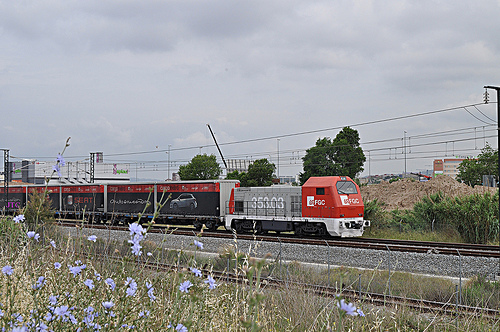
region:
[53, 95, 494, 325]
a train on tracks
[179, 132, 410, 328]
tracks with a train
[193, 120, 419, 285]
train tracks with a train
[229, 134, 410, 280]
a silver and red train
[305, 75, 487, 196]
power lines in the air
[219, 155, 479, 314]
train tracks with rocks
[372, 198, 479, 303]
rocks surrounding tracks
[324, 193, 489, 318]
rocks surround train tracks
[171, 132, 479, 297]
train tracks with train cars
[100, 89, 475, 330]
train cars on a track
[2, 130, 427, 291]
Train moving through the countryside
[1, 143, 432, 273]
Freight train delivering goods to a city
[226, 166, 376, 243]
Locomotive of a freight train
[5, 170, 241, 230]
Boxcars of a freight train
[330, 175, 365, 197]
Windshield of a freight train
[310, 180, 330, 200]
Window of a freight train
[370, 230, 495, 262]
Tracks used by freight trains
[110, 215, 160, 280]
Flower growing beside train tracks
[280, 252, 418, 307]
Grass growing beside train tracks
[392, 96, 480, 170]
Power lines running beside train tracks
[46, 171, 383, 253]
a long narrow train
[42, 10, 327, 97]
The sky is cloudy.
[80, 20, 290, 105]
The sky is overcast.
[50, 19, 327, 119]
The clouds are gray and white.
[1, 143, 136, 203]
Buildings are in the background.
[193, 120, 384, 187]
Trees are in the background.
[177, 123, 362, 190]
The trees have leaves.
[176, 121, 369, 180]
The trees are green.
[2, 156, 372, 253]
The train is long.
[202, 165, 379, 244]
The train is red and white.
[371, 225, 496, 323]
Two sets of train tracks.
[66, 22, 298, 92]
The clouds are blue, white and gray.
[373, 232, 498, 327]
Two sets of railroad tracks.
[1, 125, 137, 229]
A building is in the background.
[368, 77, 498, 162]
Power lines are above.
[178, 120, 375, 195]
The trees have leaves on them.